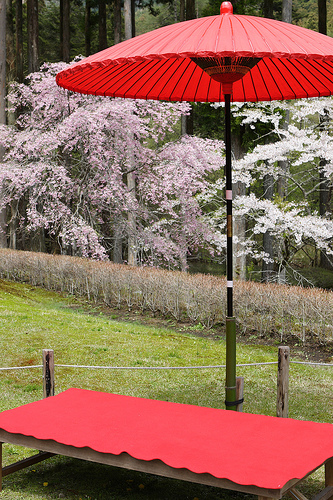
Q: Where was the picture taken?
A: It was taken at the forest.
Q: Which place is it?
A: It is a forest.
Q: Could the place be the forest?
A: Yes, it is the forest.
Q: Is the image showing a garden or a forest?
A: It is showing a forest.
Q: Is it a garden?
A: No, it is a forest.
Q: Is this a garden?
A: No, it is a forest.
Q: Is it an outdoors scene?
A: Yes, it is outdoors.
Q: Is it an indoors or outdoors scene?
A: It is outdoors.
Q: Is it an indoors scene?
A: No, it is outdoors.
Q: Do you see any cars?
A: No, there are no cars.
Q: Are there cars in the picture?
A: No, there are no cars.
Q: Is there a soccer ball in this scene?
A: No, there are no soccer balls.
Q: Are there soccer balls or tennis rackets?
A: No, there are no soccer balls or tennis rackets.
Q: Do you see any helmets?
A: No, there are no helmets.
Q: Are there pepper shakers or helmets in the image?
A: No, there are no helmets or pepper shakers.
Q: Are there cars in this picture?
A: No, there are no cars.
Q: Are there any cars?
A: No, there are no cars.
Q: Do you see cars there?
A: No, there are no cars.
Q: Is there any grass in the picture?
A: Yes, there is grass.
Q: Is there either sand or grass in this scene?
A: Yes, there is grass.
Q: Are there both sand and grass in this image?
A: No, there is grass but no sand.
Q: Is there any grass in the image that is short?
A: Yes, there is short grass.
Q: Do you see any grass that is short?
A: Yes, there is grass that is short.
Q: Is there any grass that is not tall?
A: Yes, there is short grass.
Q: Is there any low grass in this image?
A: Yes, there is low grass.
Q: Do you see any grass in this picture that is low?
A: Yes, there is grass that is low.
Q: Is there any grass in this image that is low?
A: Yes, there is grass that is low.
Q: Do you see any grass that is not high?
A: Yes, there is low grass.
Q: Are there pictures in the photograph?
A: No, there are no pictures.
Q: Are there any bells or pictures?
A: No, there are no pictures or bells.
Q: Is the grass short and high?
A: No, the grass is short but low.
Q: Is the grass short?
A: Yes, the grass is short.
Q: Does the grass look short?
A: Yes, the grass is short.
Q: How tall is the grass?
A: The grass is short.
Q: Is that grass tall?
A: No, the grass is short.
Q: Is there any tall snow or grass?
A: No, there is grass but it is short.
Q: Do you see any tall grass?
A: No, there is grass but it is short.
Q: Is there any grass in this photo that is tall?
A: No, there is grass but it is short.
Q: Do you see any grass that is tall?
A: No, there is grass but it is short.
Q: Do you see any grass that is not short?
A: No, there is grass but it is short.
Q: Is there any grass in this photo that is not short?
A: No, there is grass but it is short.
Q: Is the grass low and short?
A: Yes, the grass is low and short.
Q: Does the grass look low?
A: Yes, the grass is low.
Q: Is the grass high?
A: No, the grass is low.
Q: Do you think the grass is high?
A: No, the grass is low.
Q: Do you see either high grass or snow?
A: No, there is grass but it is low.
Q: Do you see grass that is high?
A: No, there is grass but it is low.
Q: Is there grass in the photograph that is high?
A: No, there is grass but it is low.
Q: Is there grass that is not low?
A: No, there is grass but it is low.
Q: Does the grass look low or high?
A: The grass is low.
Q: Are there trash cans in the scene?
A: No, there are no trash cans.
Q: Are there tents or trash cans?
A: No, there are no trash cans or tents.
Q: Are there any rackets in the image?
A: No, there are no rackets.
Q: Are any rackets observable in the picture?
A: No, there are no rackets.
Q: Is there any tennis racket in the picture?
A: No, there are no rackets.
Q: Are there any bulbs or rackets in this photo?
A: No, there are no rackets or bulbs.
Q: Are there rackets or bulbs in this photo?
A: No, there are no rackets or bulbs.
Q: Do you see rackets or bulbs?
A: No, there are no rackets or bulbs.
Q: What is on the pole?
A: The canopy is on the pole.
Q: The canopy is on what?
A: The canopy is on the pole.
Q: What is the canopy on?
A: The canopy is on the pole.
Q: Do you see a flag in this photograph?
A: No, there are no flags.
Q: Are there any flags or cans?
A: No, there are no flags or cans.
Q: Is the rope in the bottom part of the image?
A: Yes, the rope is in the bottom of the image.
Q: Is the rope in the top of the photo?
A: No, the rope is in the bottom of the image.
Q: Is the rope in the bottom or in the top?
A: The rope is in the bottom of the image.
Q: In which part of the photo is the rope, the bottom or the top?
A: The rope is in the bottom of the image.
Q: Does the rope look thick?
A: Yes, the rope is thick.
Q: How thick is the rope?
A: The rope is thick.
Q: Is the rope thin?
A: No, the rope is thick.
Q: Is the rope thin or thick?
A: The rope is thick.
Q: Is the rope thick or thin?
A: The rope is thick.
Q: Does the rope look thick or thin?
A: The rope is thick.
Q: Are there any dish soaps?
A: No, there are no dish soaps.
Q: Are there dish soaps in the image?
A: No, there are no dish soaps.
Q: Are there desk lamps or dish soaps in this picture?
A: No, there are no dish soaps or desk lamps.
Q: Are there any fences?
A: Yes, there is a fence.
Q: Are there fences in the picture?
A: Yes, there is a fence.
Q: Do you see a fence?
A: Yes, there is a fence.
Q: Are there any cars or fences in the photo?
A: Yes, there is a fence.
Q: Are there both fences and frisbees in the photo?
A: No, there is a fence but no frisbees.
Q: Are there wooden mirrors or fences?
A: Yes, there is a wood fence.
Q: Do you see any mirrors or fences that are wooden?
A: Yes, the fence is wooden.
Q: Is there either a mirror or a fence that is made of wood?
A: Yes, the fence is made of wood.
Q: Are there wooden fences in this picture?
A: Yes, there is a wood fence.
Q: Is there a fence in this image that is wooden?
A: Yes, there is a fence that is wooden.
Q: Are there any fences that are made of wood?
A: Yes, there is a fence that is made of wood.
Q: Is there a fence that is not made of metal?
A: Yes, there is a fence that is made of wood.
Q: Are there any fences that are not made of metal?
A: Yes, there is a fence that is made of wood.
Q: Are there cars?
A: No, there are no cars.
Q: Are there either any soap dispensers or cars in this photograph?
A: No, there are no cars or soap dispensers.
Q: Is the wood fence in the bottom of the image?
A: Yes, the fence is in the bottom of the image.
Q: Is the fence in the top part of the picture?
A: No, the fence is in the bottom of the image.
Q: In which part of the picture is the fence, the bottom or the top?
A: The fence is in the bottom of the image.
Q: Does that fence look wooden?
A: Yes, the fence is wooden.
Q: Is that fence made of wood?
A: Yes, the fence is made of wood.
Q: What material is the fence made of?
A: The fence is made of wood.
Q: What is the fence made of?
A: The fence is made of wood.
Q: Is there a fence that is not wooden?
A: No, there is a fence but it is wooden.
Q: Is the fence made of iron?
A: No, the fence is made of wood.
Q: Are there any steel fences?
A: No, there is a fence but it is made of wood.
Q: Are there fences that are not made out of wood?
A: No, there is a fence but it is made of wood.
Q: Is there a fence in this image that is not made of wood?
A: No, there is a fence but it is made of wood.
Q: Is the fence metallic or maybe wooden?
A: The fence is wooden.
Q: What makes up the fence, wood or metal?
A: The fence is made of wood.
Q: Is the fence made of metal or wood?
A: The fence is made of wood.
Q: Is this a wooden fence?
A: Yes, this is a wooden fence.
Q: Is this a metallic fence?
A: No, this is a wooden fence.